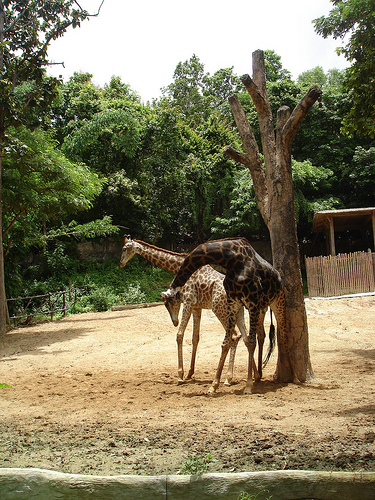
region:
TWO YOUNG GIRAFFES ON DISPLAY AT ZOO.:
[111, 224, 300, 396]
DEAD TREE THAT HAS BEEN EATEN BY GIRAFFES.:
[218, 49, 326, 391]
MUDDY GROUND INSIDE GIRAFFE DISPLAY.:
[79, 426, 325, 466]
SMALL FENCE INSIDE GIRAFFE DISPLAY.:
[300, 252, 368, 297]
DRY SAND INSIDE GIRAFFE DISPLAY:
[53, 360, 126, 403]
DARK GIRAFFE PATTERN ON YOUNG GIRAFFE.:
[228, 256, 259, 300]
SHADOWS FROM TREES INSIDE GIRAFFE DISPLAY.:
[15, 327, 78, 357]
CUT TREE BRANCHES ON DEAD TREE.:
[215, 47, 320, 170]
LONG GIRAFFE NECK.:
[108, 236, 179, 272]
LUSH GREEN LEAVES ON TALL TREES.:
[66, 87, 203, 228]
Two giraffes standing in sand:
[113, 230, 302, 397]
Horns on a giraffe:
[115, 221, 137, 252]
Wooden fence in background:
[299, 252, 373, 283]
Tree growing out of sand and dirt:
[207, 103, 358, 406]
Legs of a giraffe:
[179, 302, 201, 408]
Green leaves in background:
[7, 112, 189, 224]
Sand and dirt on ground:
[40, 351, 169, 431]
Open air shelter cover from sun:
[302, 198, 374, 249]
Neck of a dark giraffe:
[155, 242, 240, 295]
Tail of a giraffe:
[262, 305, 290, 412]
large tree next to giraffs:
[216, 48, 368, 388]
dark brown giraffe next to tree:
[162, 235, 290, 387]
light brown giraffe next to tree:
[120, 234, 237, 380]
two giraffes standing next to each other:
[118, 230, 291, 400]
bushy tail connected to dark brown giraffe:
[264, 322, 277, 378]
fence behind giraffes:
[303, 250, 372, 293]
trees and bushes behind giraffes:
[15, 111, 256, 280]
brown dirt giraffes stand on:
[46, 391, 367, 471]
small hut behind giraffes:
[306, 207, 374, 244]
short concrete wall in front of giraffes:
[0, 468, 370, 498]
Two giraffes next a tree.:
[118, 229, 306, 397]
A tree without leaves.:
[230, 46, 346, 389]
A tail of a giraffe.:
[264, 309, 280, 377]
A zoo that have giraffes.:
[16, 77, 373, 440]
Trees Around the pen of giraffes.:
[25, 120, 222, 223]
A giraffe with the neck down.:
[166, 236, 292, 395]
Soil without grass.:
[53, 332, 166, 413]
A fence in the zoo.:
[7, 293, 86, 323]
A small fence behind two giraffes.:
[306, 244, 373, 302]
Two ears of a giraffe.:
[155, 290, 188, 301]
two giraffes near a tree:
[107, 219, 296, 409]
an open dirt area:
[27, 326, 154, 447]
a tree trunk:
[234, 143, 334, 394]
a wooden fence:
[303, 250, 372, 303]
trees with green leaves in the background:
[13, 133, 115, 298]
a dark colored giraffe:
[160, 226, 284, 392]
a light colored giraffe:
[113, 228, 176, 374]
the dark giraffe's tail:
[255, 297, 285, 367]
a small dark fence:
[10, 288, 87, 325]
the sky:
[105, 2, 230, 52]